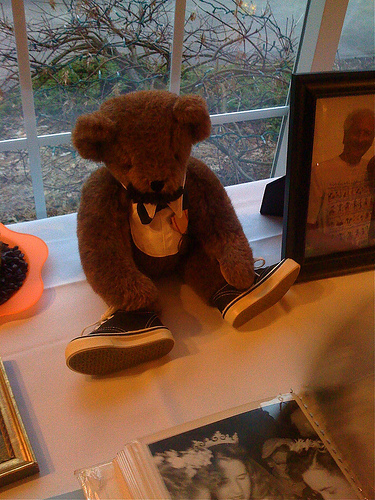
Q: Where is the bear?
A: Window shelf.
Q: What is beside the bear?
A: Picture.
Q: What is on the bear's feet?
A: Shoes.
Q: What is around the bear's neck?
A: Tie.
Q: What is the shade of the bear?
A: Brown.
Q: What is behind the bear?
A: A window.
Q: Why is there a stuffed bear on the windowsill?
A: To decorate the room.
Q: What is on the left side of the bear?
A: A framed photo.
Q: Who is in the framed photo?
A: An old man.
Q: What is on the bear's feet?
A: Shoes.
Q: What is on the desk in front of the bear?
A: A photo album.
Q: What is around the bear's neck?
A: A bow tie.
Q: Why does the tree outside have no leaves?
A: They have fallen off due to the temperature.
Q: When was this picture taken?
A: In the evening.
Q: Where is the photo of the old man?
A: In the frame.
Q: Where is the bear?
A: On the table.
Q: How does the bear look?
A: Stuffed.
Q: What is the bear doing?
A: Sitting.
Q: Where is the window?
A: Behind the bear.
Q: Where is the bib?
A: On the bear.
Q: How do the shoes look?
A: Blue and white.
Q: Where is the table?
A: Beneath the bear.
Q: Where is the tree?
A: Outside of the window.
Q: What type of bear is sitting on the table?
A: Teddy.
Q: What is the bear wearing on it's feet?
A: Shoes.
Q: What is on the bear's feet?
A: Sneakers.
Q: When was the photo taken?
A: Daytime.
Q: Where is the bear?
A: On the window sill.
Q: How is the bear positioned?
A: Sitting.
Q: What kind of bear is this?
A: A teddy bear.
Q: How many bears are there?
A: One.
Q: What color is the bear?
A: Brown.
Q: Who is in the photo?
A: Nobody.